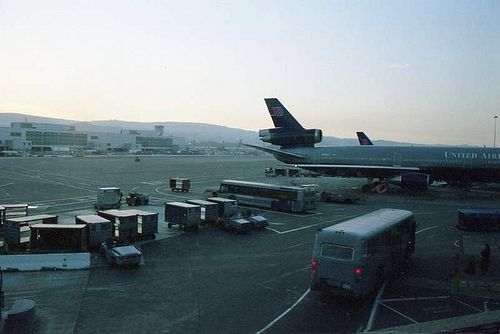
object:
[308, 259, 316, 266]
tail light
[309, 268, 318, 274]
tail light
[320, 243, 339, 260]
back window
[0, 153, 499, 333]
ground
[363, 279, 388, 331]
lines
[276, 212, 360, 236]
lines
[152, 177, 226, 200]
lines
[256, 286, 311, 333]
lines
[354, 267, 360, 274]
lights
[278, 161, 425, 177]
wing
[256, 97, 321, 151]
tail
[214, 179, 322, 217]
bus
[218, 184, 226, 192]
windows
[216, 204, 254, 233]
trucks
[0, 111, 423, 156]
mountains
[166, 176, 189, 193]
cart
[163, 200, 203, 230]
cart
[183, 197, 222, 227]
cart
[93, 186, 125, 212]
cart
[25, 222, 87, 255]
cart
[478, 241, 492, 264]
people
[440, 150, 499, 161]
writing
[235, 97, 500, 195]
plane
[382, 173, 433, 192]
engine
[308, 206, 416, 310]
bus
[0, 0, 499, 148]
sky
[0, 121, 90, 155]
building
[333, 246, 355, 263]
window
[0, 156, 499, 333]
runway